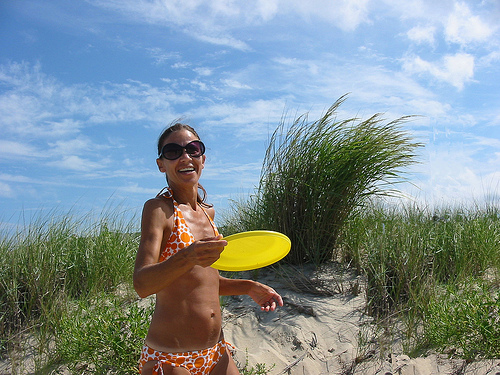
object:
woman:
[130, 122, 284, 374]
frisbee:
[203, 228, 290, 274]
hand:
[190, 234, 230, 270]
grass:
[2, 117, 495, 360]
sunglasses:
[161, 138, 208, 159]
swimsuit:
[131, 200, 238, 372]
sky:
[2, 1, 499, 222]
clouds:
[2, 1, 499, 214]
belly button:
[208, 311, 217, 319]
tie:
[152, 360, 163, 374]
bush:
[233, 93, 423, 256]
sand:
[8, 253, 500, 374]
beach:
[0, 235, 500, 373]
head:
[155, 123, 207, 187]